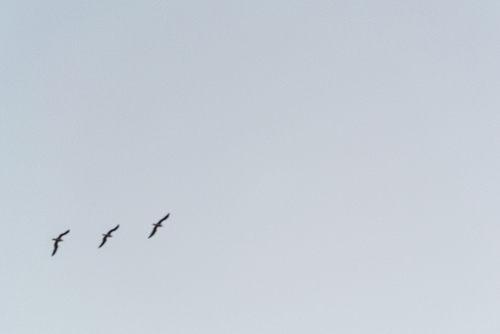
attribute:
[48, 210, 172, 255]
birds — flying, together, small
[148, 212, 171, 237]
bird — flying, brown, small, little, black, dark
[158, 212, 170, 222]
wing — curved, straight, black, small, dark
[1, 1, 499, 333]
sky — blue, clear, grey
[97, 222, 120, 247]
bird — middle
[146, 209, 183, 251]
bird — black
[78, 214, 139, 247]
bird — black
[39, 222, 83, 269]
bird — black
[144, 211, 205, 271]
bird — black